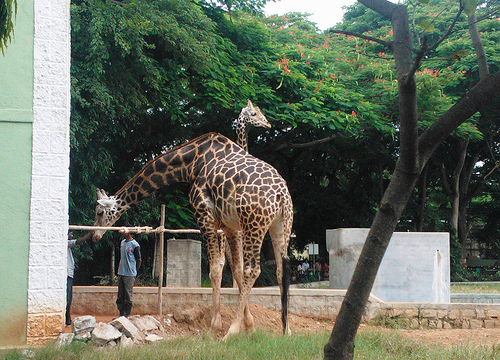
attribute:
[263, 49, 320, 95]
flowers — red 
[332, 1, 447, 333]
trunk — brown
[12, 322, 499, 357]
grass — green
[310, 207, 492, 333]
wall — bricks and stone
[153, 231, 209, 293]
pillar — large, made of gray bricks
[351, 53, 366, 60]
flower — orange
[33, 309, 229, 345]
rocks — white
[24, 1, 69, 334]
stone wall — white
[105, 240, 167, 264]
shirt — blue 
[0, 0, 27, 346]
wall — painted green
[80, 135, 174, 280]
neck — long 